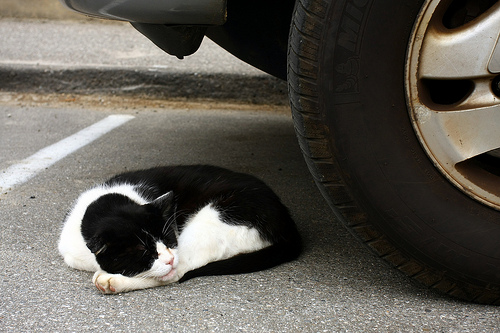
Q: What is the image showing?
A: It is showing a pavement.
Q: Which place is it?
A: It is a pavement.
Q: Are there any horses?
A: No, there are no horses.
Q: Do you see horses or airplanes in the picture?
A: No, there are no horses or airplanes.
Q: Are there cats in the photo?
A: Yes, there is a cat.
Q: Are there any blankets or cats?
A: Yes, there is a cat.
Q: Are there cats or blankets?
A: Yes, there is a cat.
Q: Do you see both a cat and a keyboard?
A: No, there is a cat but no keyboards.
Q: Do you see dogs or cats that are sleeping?
A: Yes, the cat is sleeping.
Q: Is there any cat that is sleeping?
A: Yes, there is a cat that is sleeping.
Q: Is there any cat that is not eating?
A: Yes, there is a cat that is sleeping.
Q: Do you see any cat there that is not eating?
A: Yes, there is a cat that is sleeping .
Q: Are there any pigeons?
A: No, there are no pigeons.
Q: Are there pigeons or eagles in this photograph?
A: No, there are no pigeons or eagles.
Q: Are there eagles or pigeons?
A: No, there are no pigeons or eagles.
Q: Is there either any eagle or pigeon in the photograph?
A: No, there are no pigeons or eagles.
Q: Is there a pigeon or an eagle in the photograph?
A: No, there are no pigeons or eagles.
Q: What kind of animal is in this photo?
A: The animal is a cat.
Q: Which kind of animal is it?
A: The animal is a cat.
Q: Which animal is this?
A: That is a cat.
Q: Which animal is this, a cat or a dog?
A: That is a cat.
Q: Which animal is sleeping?
A: The animal is a cat.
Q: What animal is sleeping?
A: The animal is a cat.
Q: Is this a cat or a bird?
A: This is a cat.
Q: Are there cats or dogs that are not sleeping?
A: No, there is a cat but it is sleeping.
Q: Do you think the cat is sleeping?
A: Yes, the cat is sleeping.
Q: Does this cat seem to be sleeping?
A: Yes, the cat is sleeping.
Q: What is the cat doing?
A: The cat is sleeping.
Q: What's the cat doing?
A: The cat is sleeping.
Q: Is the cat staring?
A: No, the cat is sleeping.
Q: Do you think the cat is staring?
A: No, the cat is sleeping.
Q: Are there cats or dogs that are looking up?
A: No, there is a cat but it is sleeping.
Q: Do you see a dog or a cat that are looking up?
A: No, there is a cat but it is sleeping.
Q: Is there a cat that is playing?
A: No, there is a cat but it is sleeping.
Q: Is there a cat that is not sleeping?
A: No, there is a cat but it is sleeping.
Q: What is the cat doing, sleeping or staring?
A: The cat is sleeping.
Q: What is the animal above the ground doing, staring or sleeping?
A: The cat is sleeping.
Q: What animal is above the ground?
A: The animal is a cat.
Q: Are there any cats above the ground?
A: Yes, there is a cat above the ground.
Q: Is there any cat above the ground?
A: Yes, there is a cat above the ground.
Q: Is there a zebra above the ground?
A: No, there is a cat above the ground.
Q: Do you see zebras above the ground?
A: No, there is a cat above the ground.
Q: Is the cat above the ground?
A: Yes, the cat is above the ground.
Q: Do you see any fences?
A: No, there are no fences.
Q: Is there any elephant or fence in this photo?
A: No, there are no fences or elephants.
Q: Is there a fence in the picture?
A: No, there are no fences.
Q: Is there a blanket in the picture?
A: No, there are no blankets.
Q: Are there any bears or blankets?
A: No, there are no blankets or bears.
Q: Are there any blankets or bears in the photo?
A: No, there are no blankets or bears.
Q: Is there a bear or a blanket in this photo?
A: No, there are no blankets or bears.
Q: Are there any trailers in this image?
A: No, there are no trailers.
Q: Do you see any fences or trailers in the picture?
A: No, there are no trailers or fences.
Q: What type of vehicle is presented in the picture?
A: The vehicle is a car.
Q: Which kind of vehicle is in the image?
A: The vehicle is a car.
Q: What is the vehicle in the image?
A: The vehicle is a car.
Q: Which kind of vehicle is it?
A: The vehicle is a car.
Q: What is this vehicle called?
A: That is a car.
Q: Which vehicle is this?
A: That is a car.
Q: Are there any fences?
A: No, there are no fences.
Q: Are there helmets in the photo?
A: No, there are no helmets.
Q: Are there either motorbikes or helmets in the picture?
A: No, there are no helmets or motorbikes.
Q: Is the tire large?
A: Yes, the tire is large.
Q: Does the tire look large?
A: Yes, the tire is large.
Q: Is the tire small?
A: No, the tire is large.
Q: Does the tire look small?
A: No, the tire is large.